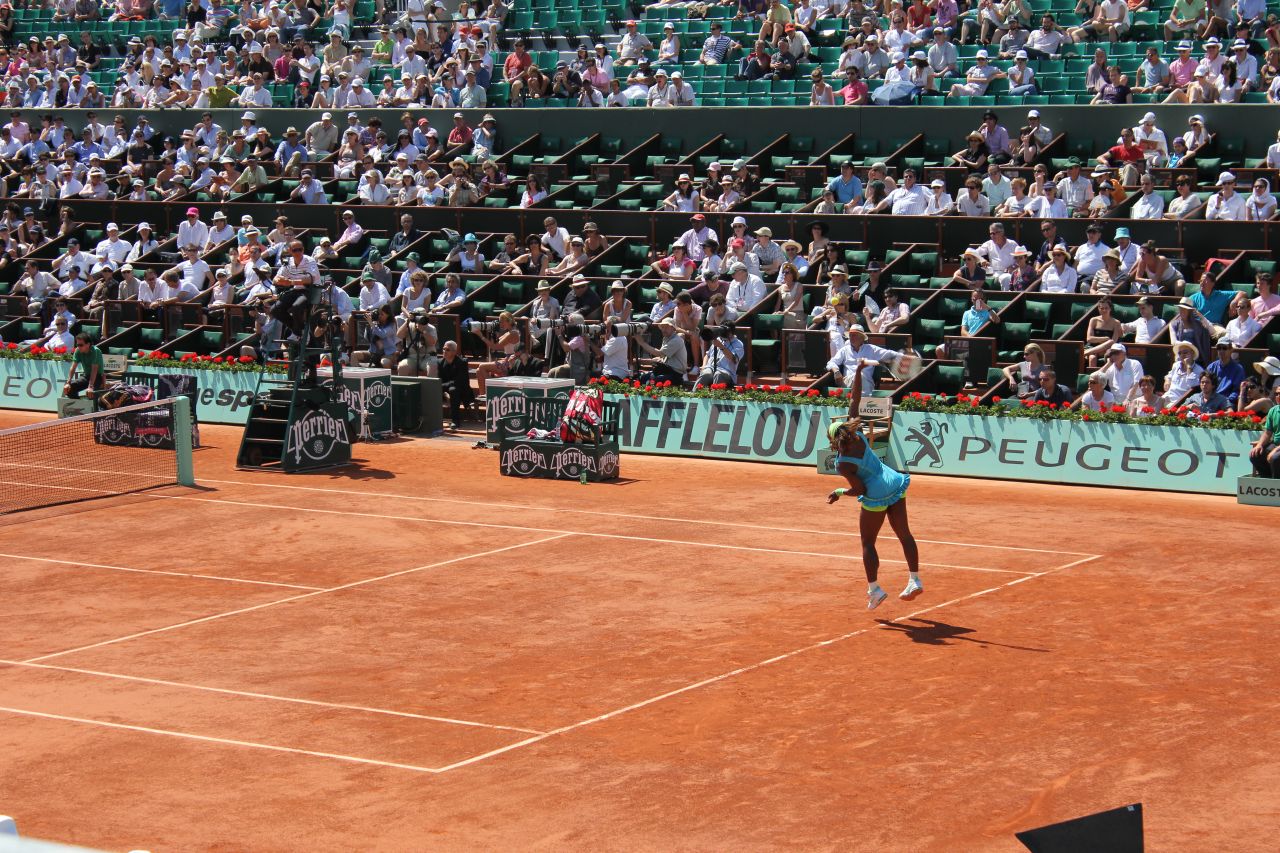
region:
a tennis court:
[86, 495, 656, 747]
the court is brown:
[501, 563, 658, 681]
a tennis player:
[814, 418, 960, 602]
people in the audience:
[1061, 223, 1243, 435]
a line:
[444, 702, 539, 738]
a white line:
[271, 733, 422, 776]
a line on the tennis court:
[627, 680, 747, 709]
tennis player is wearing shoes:
[898, 583, 932, 599]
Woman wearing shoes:
[844, 566, 931, 619]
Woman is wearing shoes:
[852, 570, 954, 610]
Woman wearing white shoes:
[842, 563, 931, 619]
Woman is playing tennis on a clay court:
[811, 312, 951, 624]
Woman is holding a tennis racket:
[839, 330, 939, 397]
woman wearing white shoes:
[845, 571, 929, 609]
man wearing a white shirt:
[721, 267, 753, 307]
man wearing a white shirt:
[1101, 353, 1139, 393]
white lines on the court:
[75, 666, 583, 790]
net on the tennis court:
[11, 393, 177, 515]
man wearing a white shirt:
[352, 179, 394, 204]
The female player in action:
[822, 399, 944, 605]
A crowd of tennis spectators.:
[3, 4, 1277, 411]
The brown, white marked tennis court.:
[0, 405, 1277, 849]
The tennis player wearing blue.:
[824, 354, 933, 611]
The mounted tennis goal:
[1, 396, 193, 516]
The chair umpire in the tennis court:
[243, 240, 354, 470]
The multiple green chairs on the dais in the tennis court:
[0, 0, 1277, 406]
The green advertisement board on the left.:
[1, 363, 291, 419]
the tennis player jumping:
[821, 420, 928, 613]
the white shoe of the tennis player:
[861, 585, 884, 614]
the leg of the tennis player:
[855, 499, 886, 588]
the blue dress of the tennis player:
[837, 437, 910, 510]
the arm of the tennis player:
[832, 455, 864, 500]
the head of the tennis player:
[828, 417, 860, 448]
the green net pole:
[170, 393, 195, 491]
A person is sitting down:
[1030, 250, 1077, 293]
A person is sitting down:
[715, 256, 769, 327]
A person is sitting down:
[746, 215, 786, 280]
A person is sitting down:
[984, 221, 1057, 285]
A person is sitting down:
[1077, 224, 1113, 277]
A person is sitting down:
[1116, 301, 1154, 337]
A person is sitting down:
[1087, 351, 1163, 413]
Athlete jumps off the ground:
[814, 412, 943, 622]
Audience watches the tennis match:
[11, 7, 1274, 829]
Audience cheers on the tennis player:
[11, 0, 1250, 833]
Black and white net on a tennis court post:
[4, 391, 217, 522]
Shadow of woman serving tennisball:
[873, 609, 1059, 658]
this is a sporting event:
[23, 27, 1248, 837]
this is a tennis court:
[95, 439, 672, 746]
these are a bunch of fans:
[148, 5, 844, 432]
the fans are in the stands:
[252, 71, 990, 361]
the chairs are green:
[548, 5, 899, 136]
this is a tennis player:
[749, 232, 1036, 744]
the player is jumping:
[696, 274, 1083, 617]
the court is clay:
[153, 490, 363, 614]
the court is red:
[40, 439, 745, 848]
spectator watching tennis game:
[1026, 364, 1069, 406]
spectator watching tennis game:
[1044, 242, 1075, 291]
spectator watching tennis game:
[574, 214, 608, 257]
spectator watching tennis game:
[592, 313, 637, 377]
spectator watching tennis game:
[704, 313, 747, 393]